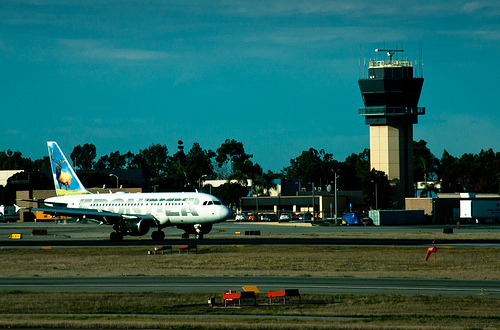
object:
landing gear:
[192, 232, 205, 239]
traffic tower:
[354, 41, 429, 186]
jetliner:
[15, 140, 230, 242]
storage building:
[360, 209, 423, 226]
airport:
[0, 223, 499, 329]